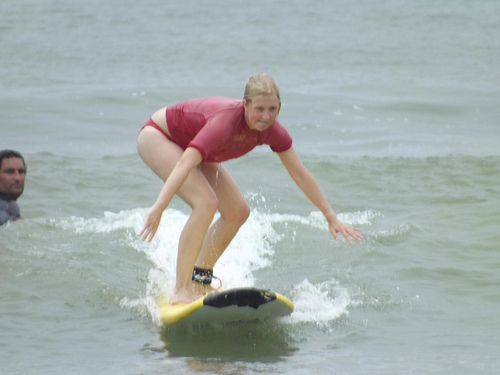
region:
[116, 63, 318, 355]
girl on a surfboard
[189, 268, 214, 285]
band around the ankle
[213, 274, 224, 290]
rope to the surfboard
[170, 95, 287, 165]
girl wearing a red tshirt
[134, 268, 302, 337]
yellow surfboard in the ocean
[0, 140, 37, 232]
man in the water looking at the girl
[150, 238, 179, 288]
water breaking behind the surfboard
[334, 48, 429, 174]
dark ocean water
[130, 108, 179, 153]
red bathing suit on the girl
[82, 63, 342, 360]
girl surfing in the ocean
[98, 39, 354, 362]
Girl in the water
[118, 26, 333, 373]
Girl on a surfboard in the water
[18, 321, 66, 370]
Small ripples in the water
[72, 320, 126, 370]
Small ripples in the water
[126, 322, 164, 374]
Small ripples in the water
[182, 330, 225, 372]
Small ripples in the water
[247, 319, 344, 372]
Small ripples in the water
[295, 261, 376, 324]
Small ripples in the water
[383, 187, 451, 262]
Small ripples in the water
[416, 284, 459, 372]
Small ripples in the water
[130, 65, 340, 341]
a woman surfing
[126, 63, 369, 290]
a woman in a red shirt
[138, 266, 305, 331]
a yellow surfboard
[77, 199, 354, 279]
the waves of the surfboard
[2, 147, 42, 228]
a man watching the woman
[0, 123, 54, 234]
a man in the water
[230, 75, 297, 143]
the face of the woman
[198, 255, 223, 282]
the ankle bracelet of the surfboard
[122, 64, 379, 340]
a woman standing on the surfboard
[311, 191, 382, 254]
the hand of the woman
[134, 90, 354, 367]
A girl is on a surf board.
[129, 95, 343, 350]
A girl is surfing.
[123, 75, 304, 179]
A girl is wearing a red shirt.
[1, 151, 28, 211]
A guy is watching a girl surf.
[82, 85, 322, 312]
A girl is balancing on a surfboard.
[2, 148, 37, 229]
A guy is in the ocean.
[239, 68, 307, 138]
A girl has wet blonde hair.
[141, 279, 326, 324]
A girl is on a yellow surf board.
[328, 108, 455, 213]
The ocean has small waves.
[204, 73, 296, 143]
A girl is bitting her lip.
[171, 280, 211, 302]
The woman is not wearing shoes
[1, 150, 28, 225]
A man in the water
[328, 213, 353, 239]
The left hand of th woman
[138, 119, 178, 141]
The woman is wearing bikini underwear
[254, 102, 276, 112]
The eyes of the woman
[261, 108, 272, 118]
The nose of the woman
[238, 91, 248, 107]
The right ear of the woman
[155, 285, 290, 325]
A yellow surfboard on the water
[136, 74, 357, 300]
A woman standing on a surfboard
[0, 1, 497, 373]
A body of water beneath the woman